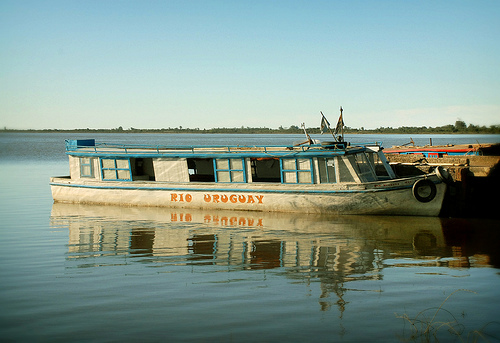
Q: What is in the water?
A: A boat.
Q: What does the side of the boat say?
A: Rio Uruguay.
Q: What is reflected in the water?
A: The boat.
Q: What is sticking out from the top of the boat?
A: Two flags.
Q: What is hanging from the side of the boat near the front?
A: A tire.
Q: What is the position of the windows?
A: Open.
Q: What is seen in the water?
A: Reflection of the boat.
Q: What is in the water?
A: A boat.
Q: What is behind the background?
A: Trees.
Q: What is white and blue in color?
A: A boat.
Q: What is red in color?
A: Name of the boat.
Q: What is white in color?
A: The boat.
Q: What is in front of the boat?
A: A tyre.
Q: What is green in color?
A: Trees.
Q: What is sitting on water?
A: Boat.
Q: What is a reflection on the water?
A: Boat.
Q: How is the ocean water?
A: Calm.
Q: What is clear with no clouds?
A: Sky.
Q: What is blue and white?
A: Boat.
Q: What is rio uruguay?
A: Boat name.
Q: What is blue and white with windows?
A: Boat.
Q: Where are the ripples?
A: On water.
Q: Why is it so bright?
A: Sunny.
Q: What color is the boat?
A: White.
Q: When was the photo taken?
A: Day time.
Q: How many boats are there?
A: One.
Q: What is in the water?
A: The boat.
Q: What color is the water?
A: Blue.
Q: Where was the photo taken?
A: On the water.